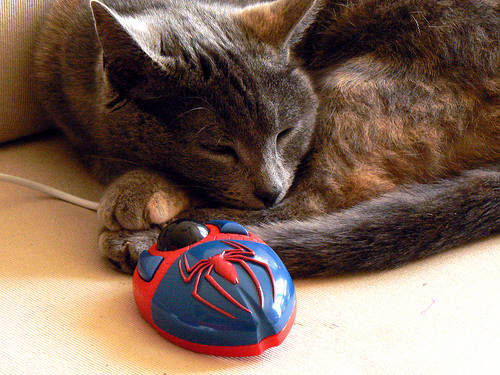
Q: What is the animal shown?
A: Cat.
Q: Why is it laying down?
A: Sleeping.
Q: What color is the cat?
A: Gray.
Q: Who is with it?
A: No one.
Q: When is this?
A: Daytime.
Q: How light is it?
A: Pretty light.